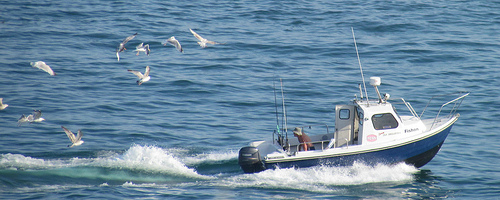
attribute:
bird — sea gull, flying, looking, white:
[160, 33, 184, 56]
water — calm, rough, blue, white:
[2, 2, 500, 197]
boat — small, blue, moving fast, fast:
[226, 57, 463, 183]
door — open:
[334, 100, 355, 146]